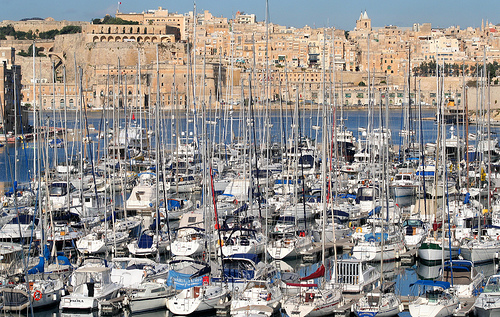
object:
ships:
[122, 62, 179, 259]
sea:
[91, 113, 457, 143]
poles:
[243, 71, 251, 217]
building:
[85, 14, 182, 43]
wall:
[87, 41, 157, 66]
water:
[0, 141, 66, 182]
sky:
[188, 0, 499, 28]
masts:
[197, 104, 204, 284]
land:
[0, 9, 499, 108]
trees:
[103, 16, 124, 26]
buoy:
[129, 111, 136, 122]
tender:
[69, 255, 113, 286]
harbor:
[236, 120, 284, 142]